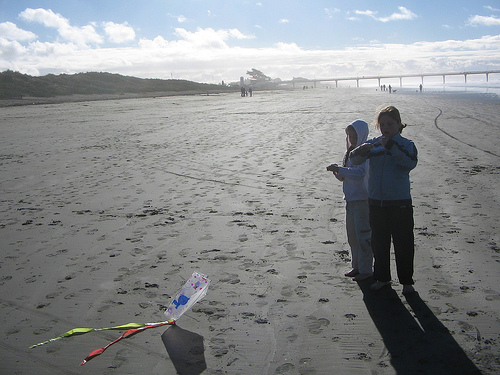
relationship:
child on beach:
[324, 117, 369, 282] [0, 89, 498, 371]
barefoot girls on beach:
[347, 105, 419, 296] [0, 89, 498, 371]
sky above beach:
[1, 3, 499, 95] [0, 89, 498, 371]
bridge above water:
[278, 68, 500, 91] [366, 75, 498, 94]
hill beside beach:
[1, 72, 228, 103] [0, 89, 498, 371]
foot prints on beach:
[331, 337, 341, 343] [0, 89, 498, 371]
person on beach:
[247, 84, 253, 96] [0, 89, 498, 371]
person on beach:
[417, 81, 423, 91] [0, 89, 498, 371]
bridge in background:
[278, 68, 500, 91] [7, 11, 492, 142]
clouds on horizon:
[0, 7, 497, 72] [2, 70, 497, 101]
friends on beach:
[377, 84, 392, 96] [384, 92, 476, 106]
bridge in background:
[247, 68, 496, 92] [52, 15, 489, 110]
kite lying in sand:
[34, 267, 221, 369] [239, 276, 319, 340]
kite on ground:
[28, 269, 214, 367] [1, 80, 499, 370]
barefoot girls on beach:
[323, 104, 416, 289] [0, 89, 498, 371]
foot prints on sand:
[210, 95, 341, 368] [0, 111, 498, 373]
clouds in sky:
[0, 7, 500, 71] [0, 0, 496, 80]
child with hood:
[325, 118, 374, 282] [347, 116, 372, 143]